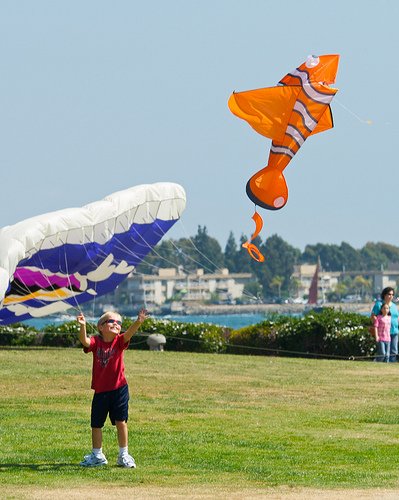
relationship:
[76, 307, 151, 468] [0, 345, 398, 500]
boy standing on grass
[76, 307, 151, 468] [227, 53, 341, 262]
boy reaching for kite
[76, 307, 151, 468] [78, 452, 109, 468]
boy has shoe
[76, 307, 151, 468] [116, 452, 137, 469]
boy has shoe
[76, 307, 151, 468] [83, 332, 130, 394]
boy has shirt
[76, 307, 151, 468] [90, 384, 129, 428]
boy has shorts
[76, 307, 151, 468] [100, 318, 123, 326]
boy has sunglasses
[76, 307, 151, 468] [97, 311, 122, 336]
boy has hair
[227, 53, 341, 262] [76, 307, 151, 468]
kite above boy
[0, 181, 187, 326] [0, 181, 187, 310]
kite has edge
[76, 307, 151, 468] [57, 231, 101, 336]
boy holding string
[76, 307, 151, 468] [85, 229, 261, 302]
boy holding string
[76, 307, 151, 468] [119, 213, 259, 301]
boy holding string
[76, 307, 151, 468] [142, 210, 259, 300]
boy holding string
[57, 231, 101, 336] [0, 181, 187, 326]
string for kite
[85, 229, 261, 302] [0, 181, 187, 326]
string for kite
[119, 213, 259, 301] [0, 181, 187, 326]
string for kite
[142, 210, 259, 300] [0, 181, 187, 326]
string for kite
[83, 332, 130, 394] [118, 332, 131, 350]
shirt has sleeve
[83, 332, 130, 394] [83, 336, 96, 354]
shirt has sleeve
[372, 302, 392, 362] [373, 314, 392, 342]
girl wearing shirt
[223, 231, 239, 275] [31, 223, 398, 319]
top on top of horizon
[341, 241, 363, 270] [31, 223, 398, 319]
top on top of horizon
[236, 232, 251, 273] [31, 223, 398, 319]
top on top of horizon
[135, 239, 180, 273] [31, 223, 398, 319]
top on top of horizon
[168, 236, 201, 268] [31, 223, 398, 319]
top on top of horizon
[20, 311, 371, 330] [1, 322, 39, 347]
water behind bush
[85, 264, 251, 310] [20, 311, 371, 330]
building overlooking water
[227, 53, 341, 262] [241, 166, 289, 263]
kite has tail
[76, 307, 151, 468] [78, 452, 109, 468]
boy wearing shoe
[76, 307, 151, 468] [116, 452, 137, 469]
boy wearing shoe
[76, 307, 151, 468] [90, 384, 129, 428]
boy wearing shorts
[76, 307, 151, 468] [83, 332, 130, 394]
boy wearing shirt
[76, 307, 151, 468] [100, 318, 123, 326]
boy wearing sunglasses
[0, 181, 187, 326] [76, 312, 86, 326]
kite inside of hand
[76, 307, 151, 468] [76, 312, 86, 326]
boy has hand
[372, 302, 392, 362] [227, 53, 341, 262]
girl watching kite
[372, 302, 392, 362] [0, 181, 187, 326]
girl watching kite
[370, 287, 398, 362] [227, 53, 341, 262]
woman watching kite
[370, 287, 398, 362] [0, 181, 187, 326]
woman watching kite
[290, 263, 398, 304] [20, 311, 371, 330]
hotel across water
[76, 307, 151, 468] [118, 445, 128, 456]
boy wearing sock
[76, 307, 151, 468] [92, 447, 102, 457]
boy wearing sock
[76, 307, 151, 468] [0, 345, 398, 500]
boy standing in grass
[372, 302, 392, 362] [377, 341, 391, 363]
girl wearing jeans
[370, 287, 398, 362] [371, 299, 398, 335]
woman wearing shirt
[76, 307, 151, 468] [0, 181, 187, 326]
boy flying kite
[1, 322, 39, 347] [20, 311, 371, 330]
bush by water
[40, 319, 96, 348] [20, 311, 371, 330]
bush by water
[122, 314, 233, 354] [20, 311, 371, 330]
bush by water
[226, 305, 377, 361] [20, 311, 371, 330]
bush by water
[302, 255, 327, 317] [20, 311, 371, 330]
boat on top of water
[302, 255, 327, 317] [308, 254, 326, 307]
boat has sail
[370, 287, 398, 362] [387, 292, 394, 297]
woman wearing sunglasses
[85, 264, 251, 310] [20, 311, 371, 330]
building by water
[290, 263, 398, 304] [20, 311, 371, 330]
hotel by water